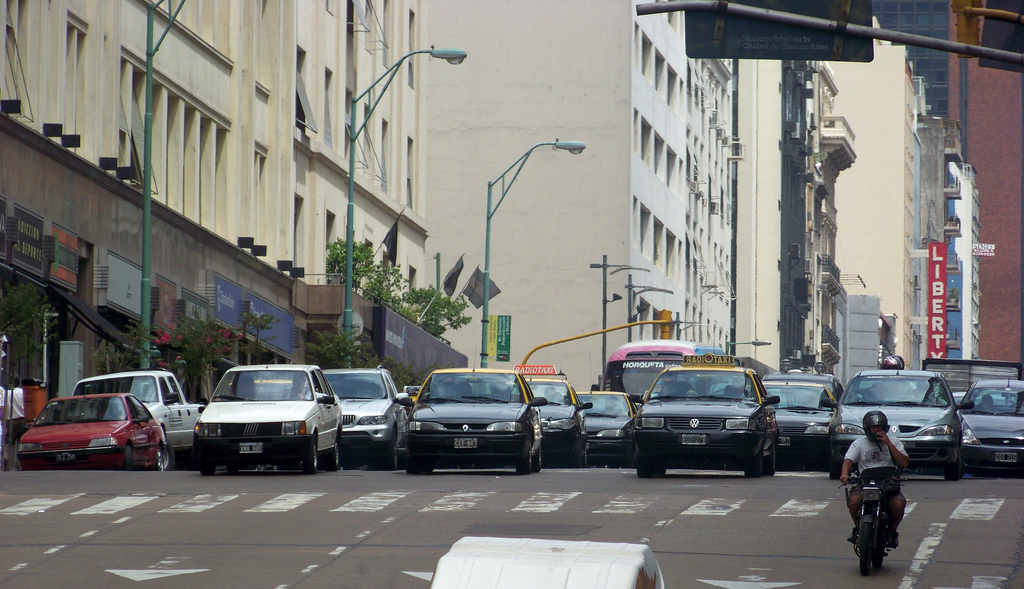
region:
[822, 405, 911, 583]
person riding on motorcycle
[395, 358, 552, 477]
black car driving down street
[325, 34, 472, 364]
green streetlight on side of street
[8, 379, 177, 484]
red car parked next to sidewalk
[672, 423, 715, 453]
license plate on front of car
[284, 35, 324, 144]
open window on side of building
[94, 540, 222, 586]
white arrow on street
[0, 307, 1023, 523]
cars on the street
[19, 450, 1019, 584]
lines on the street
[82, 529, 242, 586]
arrows on the street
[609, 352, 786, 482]
the car is black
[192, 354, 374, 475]
the car is white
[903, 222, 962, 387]
a red and white sign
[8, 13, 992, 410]
a row of buildings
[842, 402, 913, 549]
a person riding a motorcycle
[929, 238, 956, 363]
a red and white sign on a building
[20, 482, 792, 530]
white lines painted on a street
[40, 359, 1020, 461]
several cars on a street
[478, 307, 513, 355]
a green and yellow sign on a pole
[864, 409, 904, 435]
a man wearing a helmet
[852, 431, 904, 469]
a man wearing a white shirt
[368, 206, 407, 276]
a black flag on a flag pole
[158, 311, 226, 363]
a green tree with red flowers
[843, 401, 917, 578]
man riding a motor scooter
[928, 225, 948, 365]
White Liberty on red background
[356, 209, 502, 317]
flag fly on a building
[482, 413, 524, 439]
Headlight of a car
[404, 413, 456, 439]
Headlight of a car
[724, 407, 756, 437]
Headlight of a car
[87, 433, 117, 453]
Headlight of a car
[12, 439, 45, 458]
Headlight of a car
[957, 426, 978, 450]
Headlight of a car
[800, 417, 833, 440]
Headlight of a car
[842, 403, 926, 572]
man riding black motorcycle